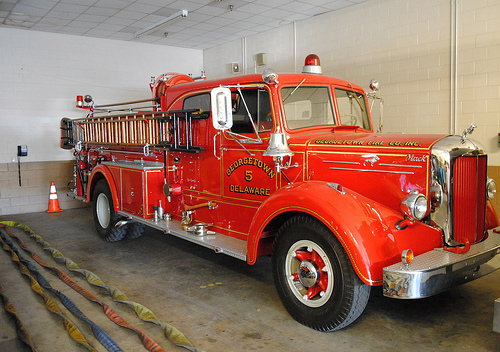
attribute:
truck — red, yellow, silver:
[32, 38, 496, 341]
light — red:
[398, 185, 432, 222]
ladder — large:
[74, 114, 196, 149]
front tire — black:
[279, 221, 341, 299]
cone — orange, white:
[43, 176, 66, 216]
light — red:
[298, 48, 321, 78]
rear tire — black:
[88, 180, 116, 227]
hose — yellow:
[36, 218, 76, 319]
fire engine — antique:
[154, 102, 364, 186]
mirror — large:
[369, 89, 383, 132]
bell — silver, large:
[261, 120, 302, 175]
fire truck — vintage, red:
[150, 108, 400, 224]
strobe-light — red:
[303, 52, 320, 66]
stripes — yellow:
[298, 141, 429, 156]